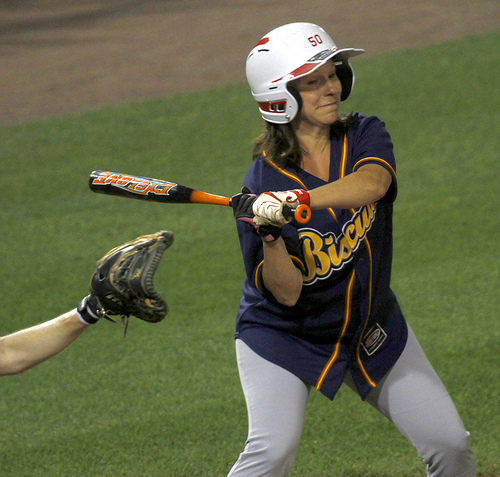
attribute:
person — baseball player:
[210, 28, 485, 475]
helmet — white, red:
[215, 2, 399, 141]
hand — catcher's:
[78, 228, 172, 324]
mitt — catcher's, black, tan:
[75, 226, 169, 322]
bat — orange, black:
[84, 163, 231, 213]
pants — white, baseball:
[219, 323, 469, 475]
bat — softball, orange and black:
[85, 165, 313, 227]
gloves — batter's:
[237, 184, 303, 225]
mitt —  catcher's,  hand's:
[78, 225, 178, 325]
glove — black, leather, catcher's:
[61, 236, 259, 428]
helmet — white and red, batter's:
[244, 17, 368, 126]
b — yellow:
[296, 223, 333, 283]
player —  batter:
[246, 24, 361, 266]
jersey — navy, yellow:
[231, 109, 412, 409]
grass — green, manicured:
[80, 343, 204, 422]